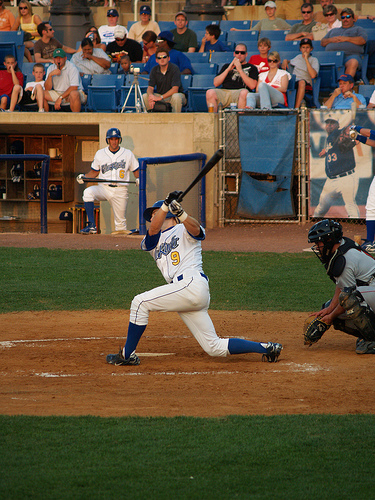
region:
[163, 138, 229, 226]
The bat is black.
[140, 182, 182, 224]
The helmet is blue.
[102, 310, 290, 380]
The socks are blue.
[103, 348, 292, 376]
His shoes are black.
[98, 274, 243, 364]
His pants are white.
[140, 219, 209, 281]
The shirt is white.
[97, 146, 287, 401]
He is swinging his bat.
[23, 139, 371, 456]
They are playing baseball.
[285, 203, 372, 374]
The catcher is kneeling.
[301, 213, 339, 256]
He is wearing a helmet.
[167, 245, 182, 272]
number on the jersey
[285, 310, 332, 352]
mit of the catcher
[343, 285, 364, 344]
arms of the catcher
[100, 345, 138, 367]
foot of the player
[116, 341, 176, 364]
base under the player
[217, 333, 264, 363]
blue sock of the player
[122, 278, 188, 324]
stripe on the player's pants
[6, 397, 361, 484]
grass of the field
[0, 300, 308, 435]
dirt of the field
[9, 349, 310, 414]
white line on the field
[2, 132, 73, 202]
wooden storage cubicles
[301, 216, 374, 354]
catcher crouching behind batter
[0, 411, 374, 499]
section of lush green grass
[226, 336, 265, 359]
blue knee sock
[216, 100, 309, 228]
chain link gate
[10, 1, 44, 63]
woman wearing a yellow sun blouse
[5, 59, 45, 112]
child slouching down in his seat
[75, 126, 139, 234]
baseball player holding a bat horizontally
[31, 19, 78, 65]
man looking over his shoulder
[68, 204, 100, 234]
baseball bat storage rack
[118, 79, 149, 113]
A silver camera tripod stand.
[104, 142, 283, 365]
A man swinging a baseball bat.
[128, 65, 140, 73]
A small camera.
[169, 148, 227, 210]
A black baseball bat.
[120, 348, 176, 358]
The home plate.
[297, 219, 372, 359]
A catcher in a baseball game.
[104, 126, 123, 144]
A blue baseball helmet.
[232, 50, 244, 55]
A black pair of sunglasses.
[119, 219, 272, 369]
A white and blue baseball uniform.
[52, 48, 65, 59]
A green ball cap.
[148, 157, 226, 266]
the man is swinging the bat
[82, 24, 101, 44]
the lady is drinking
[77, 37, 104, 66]
the man is coughing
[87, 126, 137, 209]
the man is holding the bat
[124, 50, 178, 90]
the guy is recording the game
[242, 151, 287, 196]
the tarp has a tear in it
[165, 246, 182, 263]
the number is yellow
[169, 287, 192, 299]
the pants are white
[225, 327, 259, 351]
the socks are blue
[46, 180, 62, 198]
the helmet is sitting in the cabinet hole